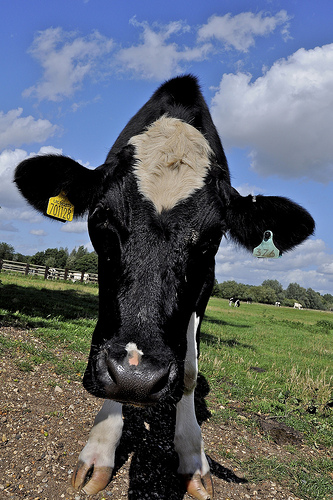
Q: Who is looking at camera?
A: Cow.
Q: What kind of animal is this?
A: A cow.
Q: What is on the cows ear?
A: A tag.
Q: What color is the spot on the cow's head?
A: White.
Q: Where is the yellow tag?
A: On the cow's ear.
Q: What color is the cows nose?
A: Black.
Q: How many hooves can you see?
A: Two.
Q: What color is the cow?
A: Black and white.